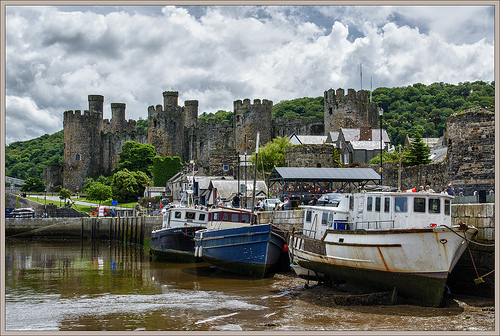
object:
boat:
[281, 181, 482, 307]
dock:
[7, 190, 499, 259]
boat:
[189, 203, 290, 272]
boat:
[141, 193, 217, 264]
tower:
[60, 91, 103, 198]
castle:
[53, 86, 500, 212]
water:
[3, 233, 499, 336]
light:
[376, 105, 386, 188]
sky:
[5, 6, 500, 147]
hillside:
[4, 129, 69, 185]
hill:
[0, 79, 500, 197]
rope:
[439, 224, 499, 247]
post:
[138, 215, 144, 247]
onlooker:
[444, 182, 456, 202]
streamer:
[267, 181, 318, 198]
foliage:
[106, 168, 150, 206]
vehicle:
[258, 195, 287, 213]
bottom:
[292, 250, 466, 314]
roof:
[265, 165, 384, 182]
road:
[23, 191, 140, 215]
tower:
[142, 89, 186, 168]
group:
[143, 88, 204, 170]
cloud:
[0, 0, 493, 90]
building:
[199, 177, 269, 209]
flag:
[269, 183, 359, 198]